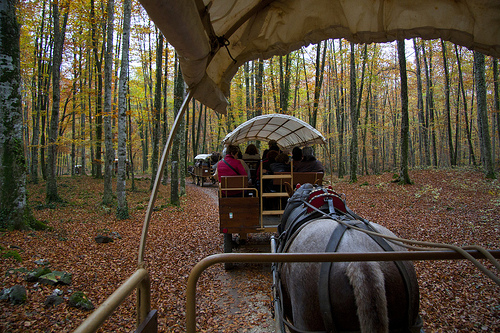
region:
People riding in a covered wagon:
[208, 109, 340, 233]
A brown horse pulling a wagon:
[126, 177, 486, 332]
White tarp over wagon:
[204, 109, 326, 155]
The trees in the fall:
[48, 2, 130, 192]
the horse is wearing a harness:
[243, 160, 440, 331]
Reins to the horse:
[365, 221, 496, 278]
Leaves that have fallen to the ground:
[38, 241, 118, 281]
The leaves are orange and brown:
[399, 194, 496, 239]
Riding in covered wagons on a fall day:
[76, 132, 310, 259]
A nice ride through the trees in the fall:
[87, 71, 267, 209]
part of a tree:
[441, 206, 465, 221]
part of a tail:
[373, 295, 378, 301]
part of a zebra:
[319, 208, 332, 283]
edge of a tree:
[409, 136, 440, 189]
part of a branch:
[321, 85, 332, 104]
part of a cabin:
[250, 123, 258, 130]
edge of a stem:
[413, 134, 418, 170]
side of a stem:
[405, 193, 410, 210]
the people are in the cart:
[207, 113, 357, 254]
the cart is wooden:
[212, 168, 335, 229]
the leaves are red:
[379, 175, 475, 247]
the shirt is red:
[212, 158, 251, 180]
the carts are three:
[179, 133, 476, 294]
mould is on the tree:
[0, 146, 47, 220]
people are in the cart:
[203, 130, 364, 211]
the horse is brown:
[268, 188, 425, 309]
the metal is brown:
[222, 240, 343, 292]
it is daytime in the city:
[4, 13, 495, 318]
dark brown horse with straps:
[271, 183, 427, 330]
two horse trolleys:
[184, 118, 336, 259]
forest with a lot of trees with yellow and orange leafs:
[33, 36, 147, 191]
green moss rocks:
[10, 254, 88, 308]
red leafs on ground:
[400, 196, 448, 218]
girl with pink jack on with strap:
[210, 143, 254, 199]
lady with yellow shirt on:
[242, 142, 262, 162]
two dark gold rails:
[119, 248, 234, 321]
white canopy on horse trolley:
[222, 103, 328, 149]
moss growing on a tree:
[5, 137, 32, 205]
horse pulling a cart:
[59, 2, 499, 327]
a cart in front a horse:
[201, 103, 341, 260]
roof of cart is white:
[209, 110, 334, 158]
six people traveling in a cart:
[211, 137, 319, 193]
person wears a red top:
[208, 139, 253, 189]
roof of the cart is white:
[145, 0, 496, 104]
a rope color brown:
[297, 202, 498, 288]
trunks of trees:
[0, 0, 498, 194]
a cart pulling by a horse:
[184, 145, 219, 191]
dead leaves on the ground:
[349, 152, 493, 232]